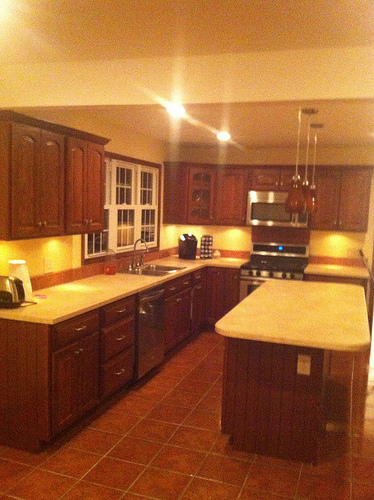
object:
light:
[167, 104, 186, 120]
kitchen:
[0, 1, 373, 499]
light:
[214, 131, 230, 148]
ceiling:
[0, 1, 373, 147]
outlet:
[44, 257, 54, 273]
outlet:
[295, 354, 311, 377]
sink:
[117, 268, 171, 279]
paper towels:
[9, 259, 35, 302]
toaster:
[1, 276, 26, 307]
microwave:
[243, 190, 309, 228]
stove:
[239, 241, 309, 304]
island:
[213, 278, 370, 464]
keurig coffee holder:
[199, 233, 215, 257]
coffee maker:
[176, 232, 198, 260]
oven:
[238, 279, 264, 302]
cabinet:
[8, 124, 66, 242]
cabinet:
[161, 159, 189, 225]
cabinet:
[248, 162, 281, 193]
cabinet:
[206, 267, 238, 328]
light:
[284, 103, 306, 215]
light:
[307, 133, 317, 214]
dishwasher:
[137, 287, 165, 382]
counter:
[212, 274, 369, 353]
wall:
[0, 234, 79, 288]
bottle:
[102, 248, 119, 274]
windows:
[83, 229, 95, 260]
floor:
[0, 327, 373, 499]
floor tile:
[129, 461, 194, 500]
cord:
[20, 301, 37, 310]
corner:
[171, 226, 221, 268]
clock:
[279, 246, 283, 249]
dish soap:
[104, 265, 118, 275]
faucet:
[130, 238, 149, 268]